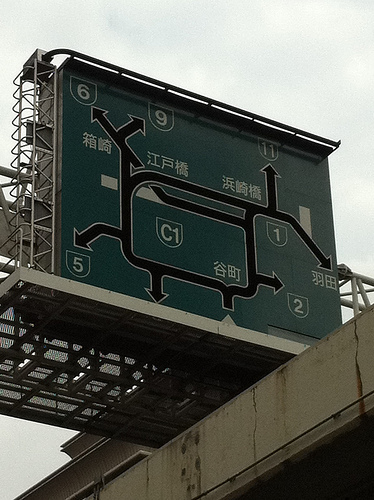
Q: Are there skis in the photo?
A: No, there are no skis.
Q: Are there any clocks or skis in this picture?
A: No, there are no skis or clocks.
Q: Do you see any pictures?
A: No, there are no pictures.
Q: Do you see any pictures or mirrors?
A: No, there are no pictures or mirrors.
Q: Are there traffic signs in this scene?
A: Yes, there is a traffic sign.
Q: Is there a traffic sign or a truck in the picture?
A: Yes, there is a traffic sign.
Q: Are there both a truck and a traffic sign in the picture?
A: No, there is a traffic sign but no trucks.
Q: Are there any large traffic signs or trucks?
A: Yes, there is a large traffic sign.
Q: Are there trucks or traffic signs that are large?
A: Yes, the traffic sign is large.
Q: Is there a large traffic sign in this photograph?
A: Yes, there is a large traffic sign.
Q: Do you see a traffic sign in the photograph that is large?
A: Yes, there is a traffic sign that is large.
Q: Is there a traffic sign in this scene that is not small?
A: Yes, there is a large traffic sign.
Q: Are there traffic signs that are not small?
A: Yes, there is a large traffic sign.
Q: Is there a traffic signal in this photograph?
A: No, there are no traffic lights.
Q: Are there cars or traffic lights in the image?
A: No, there are no traffic lights or cars.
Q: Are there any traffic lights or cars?
A: No, there are no traffic lights or cars.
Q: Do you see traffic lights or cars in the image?
A: No, there are no traffic lights or cars.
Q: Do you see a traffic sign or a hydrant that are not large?
A: No, there is a traffic sign but it is large.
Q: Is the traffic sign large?
A: Yes, the traffic sign is large.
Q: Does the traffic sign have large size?
A: Yes, the traffic sign is large.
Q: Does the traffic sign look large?
A: Yes, the traffic sign is large.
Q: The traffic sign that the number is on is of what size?
A: The traffic sign is large.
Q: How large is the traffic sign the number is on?
A: The traffic sign is large.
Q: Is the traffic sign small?
A: No, the traffic sign is large.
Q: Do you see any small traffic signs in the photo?
A: No, there is a traffic sign but it is large.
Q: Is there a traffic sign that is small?
A: No, there is a traffic sign but it is large.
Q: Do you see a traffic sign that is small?
A: No, there is a traffic sign but it is large.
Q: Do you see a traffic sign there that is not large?
A: No, there is a traffic sign but it is large.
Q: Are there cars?
A: No, there are no cars.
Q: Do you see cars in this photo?
A: No, there are no cars.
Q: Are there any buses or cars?
A: No, there are no cars or buses.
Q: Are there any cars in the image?
A: No, there are no cars.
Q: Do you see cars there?
A: No, there are no cars.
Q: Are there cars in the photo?
A: No, there are no cars.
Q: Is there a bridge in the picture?
A: Yes, there is a bridge.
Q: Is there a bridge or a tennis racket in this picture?
A: Yes, there is a bridge.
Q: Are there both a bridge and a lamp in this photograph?
A: No, there is a bridge but no lamps.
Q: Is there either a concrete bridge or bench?
A: Yes, there is a concrete bridge.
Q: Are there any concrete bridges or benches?
A: Yes, there is a concrete bridge.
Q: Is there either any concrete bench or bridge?
A: Yes, there is a concrete bridge.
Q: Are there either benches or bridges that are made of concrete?
A: Yes, the bridge is made of concrete.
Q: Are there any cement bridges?
A: Yes, there is a bridge that is made of cement.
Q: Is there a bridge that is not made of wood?
A: Yes, there is a bridge that is made of cement.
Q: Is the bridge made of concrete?
A: Yes, the bridge is made of concrete.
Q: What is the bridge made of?
A: The bridge is made of cement.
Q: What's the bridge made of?
A: The bridge is made of concrete.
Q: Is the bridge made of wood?
A: No, the bridge is made of cement.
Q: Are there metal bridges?
A: No, there is a bridge but it is made of cement.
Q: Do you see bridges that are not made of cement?
A: No, there is a bridge but it is made of cement.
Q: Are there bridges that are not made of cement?
A: No, there is a bridge but it is made of cement.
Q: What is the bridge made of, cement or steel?
A: The bridge is made of cement.